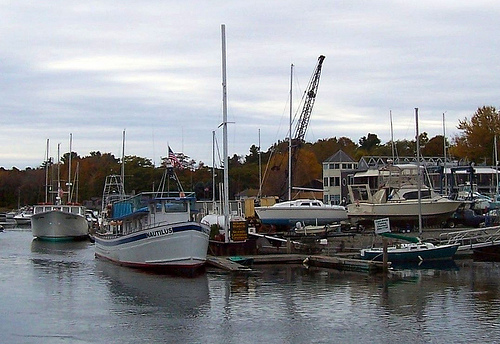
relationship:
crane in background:
[288, 52, 337, 139] [131, 50, 467, 204]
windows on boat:
[27, 202, 96, 226] [32, 133, 86, 241]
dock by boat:
[236, 239, 372, 280] [32, 229, 83, 250]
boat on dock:
[32, 133, 86, 241] [236, 239, 372, 280]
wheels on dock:
[446, 218, 466, 232] [236, 239, 372, 280]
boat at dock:
[32, 133, 86, 241] [209, 154, 494, 275]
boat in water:
[32, 133, 86, 241] [49, 275, 234, 329]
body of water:
[62, 264, 461, 344] [49, 275, 234, 329]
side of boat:
[121, 232, 164, 259] [32, 133, 86, 241]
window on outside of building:
[327, 174, 342, 186] [321, 143, 358, 206]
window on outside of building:
[327, 191, 343, 205] [321, 143, 358, 206]